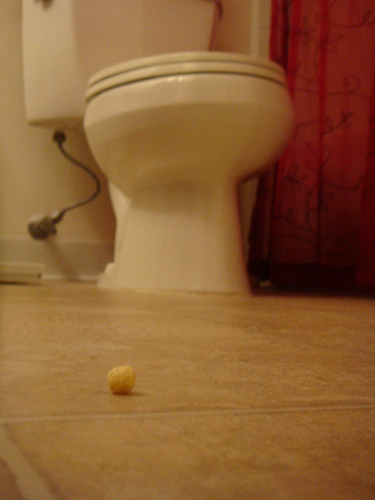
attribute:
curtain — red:
[260, 16, 371, 303]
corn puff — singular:
[105, 356, 150, 411]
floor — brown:
[4, 296, 366, 492]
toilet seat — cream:
[80, 50, 295, 297]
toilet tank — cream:
[19, 0, 226, 128]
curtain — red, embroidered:
[280, 3, 373, 291]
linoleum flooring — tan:
[2, 284, 371, 404]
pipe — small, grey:
[32, 129, 104, 250]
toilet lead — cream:
[126, 42, 291, 76]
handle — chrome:
[32, 0, 52, 10]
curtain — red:
[247, 6, 374, 292]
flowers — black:
[273, 143, 370, 275]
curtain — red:
[266, 1, 374, 292]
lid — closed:
[89, 51, 294, 83]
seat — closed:
[84, 61, 290, 106]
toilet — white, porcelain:
[80, 49, 295, 286]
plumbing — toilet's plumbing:
[17, 124, 113, 252]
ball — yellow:
[104, 360, 139, 392]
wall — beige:
[11, 126, 49, 205]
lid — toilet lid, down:
[90, 55, 286, 76]